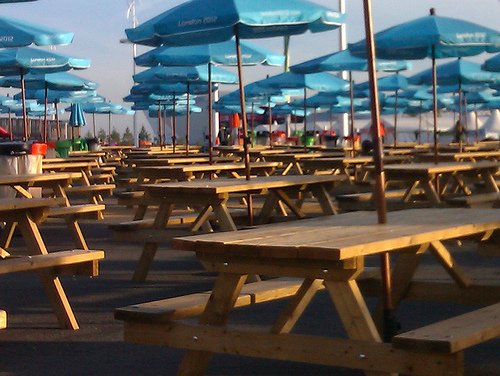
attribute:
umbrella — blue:
[133, 66, 239, 155]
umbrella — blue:
[347, 10, 499, 70]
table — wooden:
[177, 201, 494, 327]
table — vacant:
[0, 172, 115, 218]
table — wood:
[113, 207, 498, 374]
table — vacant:
[185, 201, 499, 341]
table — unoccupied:
[210, 130, 480, 362]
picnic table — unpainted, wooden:
[120, 201, 491, 375]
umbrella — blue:
[3, 46, 94, 143]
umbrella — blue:
[353, 11, 498, 60]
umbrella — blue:
[125, 1, 347, 37]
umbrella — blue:
[0, 17, 70, 51]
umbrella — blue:
[348, 6, 498, 58]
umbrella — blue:
[131, 40, 286, 67]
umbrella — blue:
[289, 49, 409, 76]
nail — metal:
[262, 119, 377, 191]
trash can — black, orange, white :
[3, 142, 33, 214]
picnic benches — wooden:
[5, 140, 498, 372]